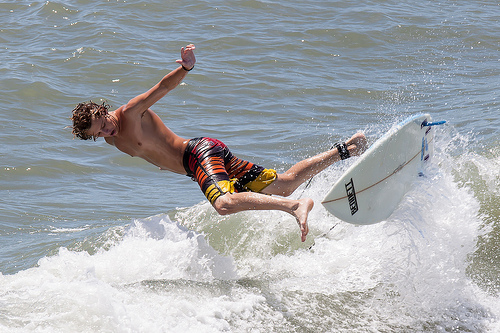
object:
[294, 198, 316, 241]
feet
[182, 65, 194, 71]
watch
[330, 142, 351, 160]
ankle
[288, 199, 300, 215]
ankle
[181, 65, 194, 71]
band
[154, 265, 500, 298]
wave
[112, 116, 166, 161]
chest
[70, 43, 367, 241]
dude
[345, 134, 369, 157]
foot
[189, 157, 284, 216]
leg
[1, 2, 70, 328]
water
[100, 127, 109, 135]
nose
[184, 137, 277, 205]
multicolored trunks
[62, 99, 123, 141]
head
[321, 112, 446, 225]
surfboard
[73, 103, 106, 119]
hair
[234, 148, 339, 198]
leg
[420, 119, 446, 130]
fin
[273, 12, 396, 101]
ocean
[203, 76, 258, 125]
water